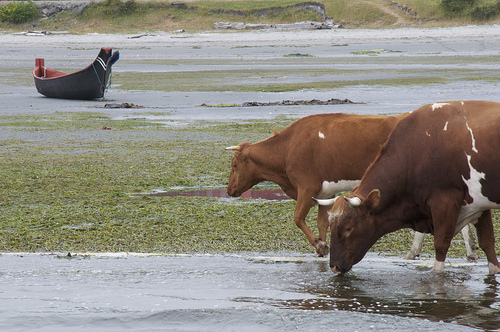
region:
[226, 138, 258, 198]
the head of the cow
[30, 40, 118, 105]
a black and red boat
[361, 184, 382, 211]
ear of the brown cow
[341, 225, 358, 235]
eye of the cow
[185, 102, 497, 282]
two brown and white cows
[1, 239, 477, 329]
water the cow is drinking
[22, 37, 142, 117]
this is a boat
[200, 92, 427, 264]
the cow is brown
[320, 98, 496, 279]
the cow is brown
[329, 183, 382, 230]
the cow has a horn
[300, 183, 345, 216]
the cow has a horn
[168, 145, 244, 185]
the cow has a horn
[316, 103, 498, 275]
cow drinking from the water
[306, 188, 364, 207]
horns on the dark brown cow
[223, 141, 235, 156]
horn on the brown cow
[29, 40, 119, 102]
black and red boat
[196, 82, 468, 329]
cows in the background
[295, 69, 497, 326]
a brown and white cow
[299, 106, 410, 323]
horns on the cow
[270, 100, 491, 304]
a cow drinking water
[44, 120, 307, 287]
grass on the ground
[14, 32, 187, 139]
a boat on the ground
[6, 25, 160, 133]
a black and red boat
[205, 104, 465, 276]
a cow walking in the background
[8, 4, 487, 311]
a dull day in the background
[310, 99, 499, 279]
brown and white cow standing in water